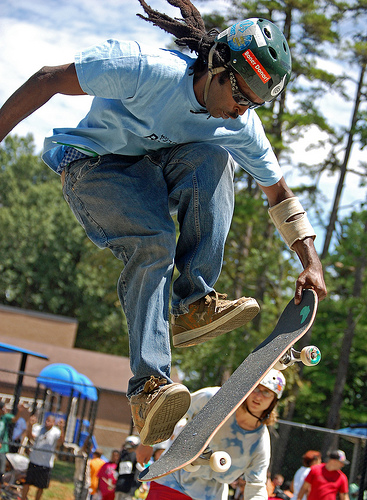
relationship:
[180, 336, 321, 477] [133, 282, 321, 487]
wheels on bottom of skateboard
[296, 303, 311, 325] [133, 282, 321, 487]
country on skateboard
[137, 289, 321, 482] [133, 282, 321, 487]
skateboard on skateboard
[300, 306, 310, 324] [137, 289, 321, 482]
country on skateboard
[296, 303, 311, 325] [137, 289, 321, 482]
country on skateboard